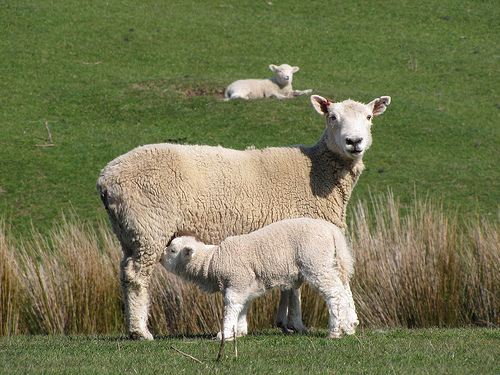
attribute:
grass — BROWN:
[6, 182, 493, 334]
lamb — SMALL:
[148, 235, 372, 329]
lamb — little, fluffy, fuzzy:
[158, 220, 364, 347]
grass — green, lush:
[17, 9, 499, 330]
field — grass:
[13, 17, 483, 98]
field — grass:
[7, 221, 485, 360]